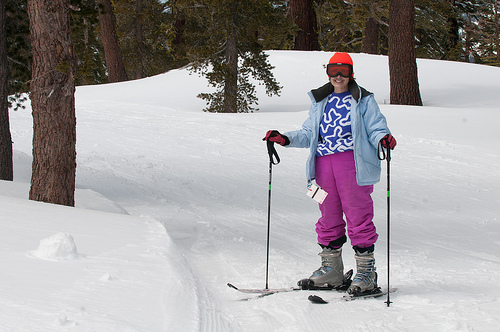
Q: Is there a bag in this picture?
A: No, there are no bags.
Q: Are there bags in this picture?
A: No, there are no bags.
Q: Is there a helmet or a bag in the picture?
A: No, there are no bags or helmets.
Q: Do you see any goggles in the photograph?
A: Yes, there are goggles.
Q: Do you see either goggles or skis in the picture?
A: Yes, there are goggles.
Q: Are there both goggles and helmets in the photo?
A: No, there are goggles but no helmets.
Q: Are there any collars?
A: Yes, there is a collar.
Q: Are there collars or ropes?
A: Yes, there is a collar.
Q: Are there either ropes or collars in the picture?
A: Yes, there is a collar.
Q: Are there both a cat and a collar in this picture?
A: No, there is a collar but no cats.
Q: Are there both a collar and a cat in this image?
A: No, there is a collar but no cats.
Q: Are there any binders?
A: No, there are no binders.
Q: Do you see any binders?
A: No, there are no binders.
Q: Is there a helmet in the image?
A: No, there are no helmets.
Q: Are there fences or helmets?
A: No, there are no helmets or fences.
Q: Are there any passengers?
A: No, there are no passengers.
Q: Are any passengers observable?
A: No, there are no passengers.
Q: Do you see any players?
A: No, there are no players.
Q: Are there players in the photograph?
A: No, there are no players.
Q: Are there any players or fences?
A: No, there are no players or fences.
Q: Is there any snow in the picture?
A: Yes, there is snow.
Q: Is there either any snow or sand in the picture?
A: Yes, there is snow.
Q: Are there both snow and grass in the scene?
A: No, there is snow but no grass.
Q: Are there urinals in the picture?
A: No, there are no urinals.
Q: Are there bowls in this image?
A: No, there are no bowls.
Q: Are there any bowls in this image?
A: No, there are no bowls.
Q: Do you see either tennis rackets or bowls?
A: No, there are no bowls or tennis rackets.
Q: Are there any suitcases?
A: No, there are no suitcases.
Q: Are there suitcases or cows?
A: No, there are no suitcases or cows.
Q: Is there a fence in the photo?
A: No, there are no fences.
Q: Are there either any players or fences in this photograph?
A: No, there are no fences or players.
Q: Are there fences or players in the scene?
A: No, there are no fences or players.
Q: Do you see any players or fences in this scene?
A: No, there are no fences or players.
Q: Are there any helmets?
A: No, there are no helmets.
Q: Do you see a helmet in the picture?
A: No, there are no helmets.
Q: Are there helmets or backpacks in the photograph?
A: No, there are no helmets or backpacks.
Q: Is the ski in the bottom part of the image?
A: Yes, the ski is in the bottom of the image.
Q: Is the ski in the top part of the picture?
A: No, the ski is in the bottom of the image.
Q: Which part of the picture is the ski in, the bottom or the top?
A: The ski is in the bottom of the image.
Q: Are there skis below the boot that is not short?
A: Yes, there is a ski below the boot.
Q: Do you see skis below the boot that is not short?
A: Yes, there is a ski below the boot.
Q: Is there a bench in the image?
A: No, there are no benches.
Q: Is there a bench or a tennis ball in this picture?
A: No, there are no benches or tennis balls.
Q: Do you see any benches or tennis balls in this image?
A: No, there are no benches or tennis balls.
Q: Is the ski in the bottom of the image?
A: Yes, the ski is in the bottom of the image.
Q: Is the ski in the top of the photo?
A: No, the ski is in the bottom of the image.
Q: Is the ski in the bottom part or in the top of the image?
A: The ski is in the bottom of the image.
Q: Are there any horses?
A: No, there are no horses.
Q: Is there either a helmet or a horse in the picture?
A: No, there are no horses or helmets.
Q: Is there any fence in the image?
A: No, there are no fences.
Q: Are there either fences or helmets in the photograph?
A: No, there are no fences or helmets.